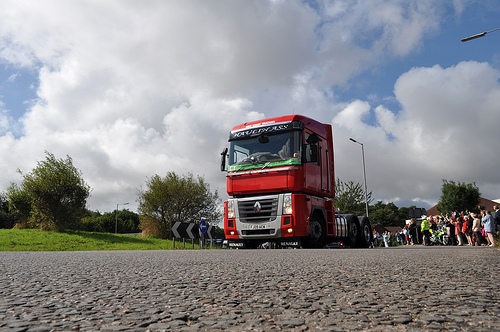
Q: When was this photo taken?
A: During the day.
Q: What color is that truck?
A: Red.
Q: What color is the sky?
A: Blue with clouds.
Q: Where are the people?
A: Standing along the truck.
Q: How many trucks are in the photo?
A: One.